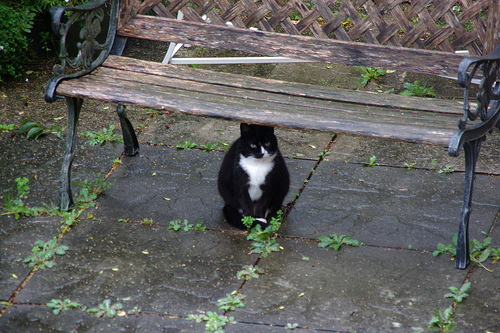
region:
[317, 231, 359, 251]
weed growing through stone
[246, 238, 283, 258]
weed growing through stone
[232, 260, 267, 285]
weed growing through stone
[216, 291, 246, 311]
weed growing through stone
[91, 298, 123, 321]
weed growing through stone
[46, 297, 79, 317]
weed growing through stone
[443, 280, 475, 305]
weed growing through stone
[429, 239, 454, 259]
weed growing through stone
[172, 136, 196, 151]
weed growing through stone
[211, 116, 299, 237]
a cat sitting under a bench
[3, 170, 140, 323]
plants growing between the tiles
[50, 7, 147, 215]
black metal legs of the bench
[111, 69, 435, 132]
brown wood slats of the bench seat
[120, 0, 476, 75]
brown patterned back of the bench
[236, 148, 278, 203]
white patch of fur on the black cat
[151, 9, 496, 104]
white metal posts behind the bench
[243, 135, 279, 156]
yellow eyes of the cat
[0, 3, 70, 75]
green bush growing next to the path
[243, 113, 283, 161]
head of a cat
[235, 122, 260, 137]
ear of a cat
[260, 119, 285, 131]
ear of a cat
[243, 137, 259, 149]
eye of a cat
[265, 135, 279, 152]
eye of a cat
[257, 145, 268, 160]
nose of a cat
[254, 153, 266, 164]
mouth of a cat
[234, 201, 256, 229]
leg of a cat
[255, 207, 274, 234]
leg of a cat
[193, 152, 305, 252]
body of a cat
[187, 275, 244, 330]
grass on the sidewalk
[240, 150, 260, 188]
white part of cat's fur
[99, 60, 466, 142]
seat of hte bench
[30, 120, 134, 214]
legs of the bench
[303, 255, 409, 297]
the ground is wet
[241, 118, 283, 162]
face of the cat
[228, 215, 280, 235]
paws of the cat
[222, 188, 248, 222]
the cat is black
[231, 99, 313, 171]
the face of a cat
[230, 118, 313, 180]
the hair of a cat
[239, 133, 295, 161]
the eyes of a cat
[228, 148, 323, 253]
the legs of a cat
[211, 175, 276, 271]
the tail of a cat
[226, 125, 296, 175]
the neck of a cat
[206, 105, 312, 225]
the body of a cat